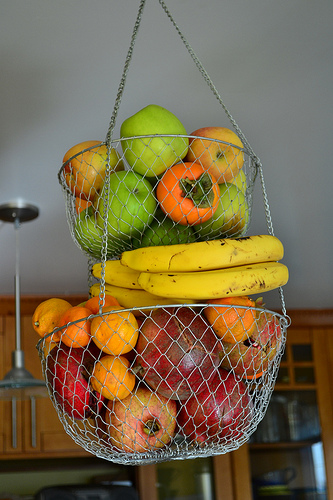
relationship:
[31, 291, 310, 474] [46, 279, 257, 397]
wire basket filled with fruit